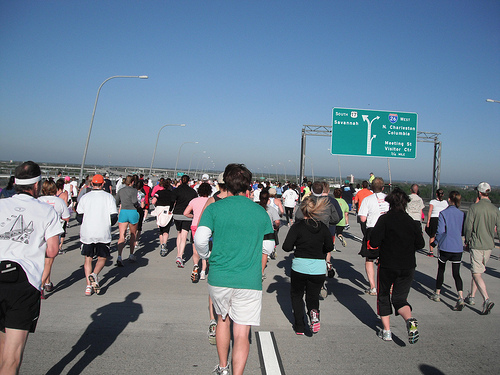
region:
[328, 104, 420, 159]
A sign indicating the road exit and routes.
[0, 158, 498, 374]
People walking in an organized event.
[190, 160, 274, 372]
A man in a green shirt.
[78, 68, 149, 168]
A street light.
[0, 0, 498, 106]
A blue sky.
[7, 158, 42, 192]
A man wearing a white headband.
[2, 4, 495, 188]
The sky is clear and blue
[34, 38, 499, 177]
Several lamp posts line the sides of the expressway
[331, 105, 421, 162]
Sign indicates a left turn to go towards Savannah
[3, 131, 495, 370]
A large crowd runs down the street for a cause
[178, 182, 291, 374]
Man wearing a white long sleeved shirt under his shirt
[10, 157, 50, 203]
Man is wearing a headband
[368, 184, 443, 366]
Jogger is wearing an all black suit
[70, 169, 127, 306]
Jogger is wearing an orange colored hat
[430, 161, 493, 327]
Couple is walking together in stride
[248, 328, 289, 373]
White lines on pavement are bordered with a black outline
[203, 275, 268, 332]
The person has white shorts on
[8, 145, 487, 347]
A crowded group of people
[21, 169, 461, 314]
Crowded group of people running together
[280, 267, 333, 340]
The woman has pants on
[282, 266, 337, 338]
The woman has black pants on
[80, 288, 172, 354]
Shadow of a person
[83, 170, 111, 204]
The person has a orange hat on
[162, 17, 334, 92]
Large body of blue skies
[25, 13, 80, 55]
white clouds in blue sky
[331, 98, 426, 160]
green and white sign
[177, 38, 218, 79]
white clouds in blue sky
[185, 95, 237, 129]
white clouds in blue sky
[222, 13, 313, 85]
white clouds in blue sky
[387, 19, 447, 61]
white clouds in blue sky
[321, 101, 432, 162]
white and green highway sign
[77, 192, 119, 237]
white shirt on runner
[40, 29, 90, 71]
white clouds in blue sky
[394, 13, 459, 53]
white clouds in blue sky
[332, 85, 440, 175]
green and white highway sign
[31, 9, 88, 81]
white clouds in blue sky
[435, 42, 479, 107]
white clouds in blue sky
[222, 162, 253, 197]
jogger has a human head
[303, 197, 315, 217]
jogger has a human head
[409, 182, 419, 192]
jogger has a human head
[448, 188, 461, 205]
jogger has a human head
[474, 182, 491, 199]
jogger has a human head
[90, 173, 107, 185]
jogger has a human head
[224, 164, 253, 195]
person has a head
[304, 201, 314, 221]
person has a head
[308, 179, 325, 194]
person has a head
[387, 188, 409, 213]
person has a head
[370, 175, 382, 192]
person has a head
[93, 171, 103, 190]
person has a head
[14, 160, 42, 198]
person has a head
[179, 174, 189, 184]
person has a head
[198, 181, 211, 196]
person has a head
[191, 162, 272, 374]
man wearing green shirt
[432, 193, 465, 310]
woman wearing purple jacket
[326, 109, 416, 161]
green and white street signs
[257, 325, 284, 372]
white line with black outline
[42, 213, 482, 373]
shadows on the road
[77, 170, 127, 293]
man wearing orange hat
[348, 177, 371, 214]
man wearing orange shirt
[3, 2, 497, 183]
clear blue sky above the runners